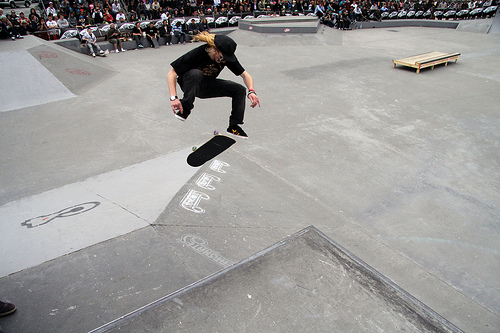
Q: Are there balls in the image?
A: No, there are no balls.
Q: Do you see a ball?
A: No, there are no balls.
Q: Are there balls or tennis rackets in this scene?
A: No, there are no balls or tennis rackets.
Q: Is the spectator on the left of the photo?
A: Yes, the spectator is on the left of the image.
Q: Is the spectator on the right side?
A: No, the spectator is on the left of the image.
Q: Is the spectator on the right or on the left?
A: The spectator is on the left of the image.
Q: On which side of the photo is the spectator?
A: The spectator is on the left of the image.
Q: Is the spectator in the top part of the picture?
A: Yes, the spectator is in the top of the image.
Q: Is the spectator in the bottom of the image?
A: No, the spectator is in the top of the image.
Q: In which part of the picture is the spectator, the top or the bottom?
A: The spectator is in the top of the image.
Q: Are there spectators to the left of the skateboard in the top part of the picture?
A: Yes, there is a spectator to the left of the skateboard.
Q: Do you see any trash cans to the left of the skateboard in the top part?
A: No, there is a spectator to the left of the skateboard.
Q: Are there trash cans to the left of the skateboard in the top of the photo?
A: No, there is a spectator to the left of the skateboard.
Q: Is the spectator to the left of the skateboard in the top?
A: Yes, the spectator is to the left of the skateboard.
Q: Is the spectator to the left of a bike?
A: No, the spectator is to the left of the skateboard.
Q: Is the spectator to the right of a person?
A: No, the spectator is to the left of a person.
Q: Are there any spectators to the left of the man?
A: Yes, there is a spectator to the left of the man.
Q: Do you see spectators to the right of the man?
A: No, the spectator is to the left of the man.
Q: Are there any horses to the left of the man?
A: No, there is a spectator to the left of the man.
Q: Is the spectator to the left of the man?
A: Yes, the spectator is to the left of the man.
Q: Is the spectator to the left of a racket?
A: No, the spectator is to the left of the man.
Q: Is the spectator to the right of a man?
A: No, the spectator is to the left of a man.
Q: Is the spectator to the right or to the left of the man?
A: The spectator is to the left of the man.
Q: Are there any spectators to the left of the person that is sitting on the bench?
A: Yes, there is a spectator to the left of the person.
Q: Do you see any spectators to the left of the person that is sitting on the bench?
A: Yes, there is a spectator to the left of the person.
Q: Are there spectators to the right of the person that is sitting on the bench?
A: No, the spectator is to the left of the person.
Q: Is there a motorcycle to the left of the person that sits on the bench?
A: No, there is a spectator to the left of the person.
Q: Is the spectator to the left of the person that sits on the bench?
A: Yes, the spectator is to the left of the person.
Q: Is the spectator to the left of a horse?
A: No, the spectator is to the left of the person.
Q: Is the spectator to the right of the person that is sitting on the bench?
A: No, the spectator is to the left of the person.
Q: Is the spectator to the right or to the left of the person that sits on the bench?
A: The spectator is to the left of the person.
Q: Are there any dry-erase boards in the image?
A: No, there are no dry-erase boards.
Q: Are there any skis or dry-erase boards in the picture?
A: No, there are no dry-erase boards or skis.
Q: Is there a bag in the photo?
A: No, there are no bags.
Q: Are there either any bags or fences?
A: No, there are no bags or fences.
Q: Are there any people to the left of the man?
A: Yes, there is a person to the left of the man.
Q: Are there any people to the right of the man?
A: No, the person is to the left of the man.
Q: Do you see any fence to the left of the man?
A: No, there is a person to the left of the man.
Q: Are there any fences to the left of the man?
A: No, there is a person to the left of the man.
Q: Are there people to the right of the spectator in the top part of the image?
A: Yes, there is a person to the right of the spectator.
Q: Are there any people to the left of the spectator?
A: No, the person is to the right of the spectator.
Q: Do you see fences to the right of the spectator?
A: No, there is a person to the right of the spectator.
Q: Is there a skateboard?
A: Yes, there is a skateboard.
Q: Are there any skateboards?
A: Yes, there is a skateboard.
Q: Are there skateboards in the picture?
A: Yes, there is a skateboard.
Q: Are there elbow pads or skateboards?
A: Yes, there is a skateboard.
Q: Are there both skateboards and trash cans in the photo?
A: No, there is a skateboard but no trash cans.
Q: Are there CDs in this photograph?
A: No, there are no cds.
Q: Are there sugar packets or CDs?
A: No, there are no CDs or sugar packets.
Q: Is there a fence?
A: No, there are no fences.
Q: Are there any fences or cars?
A: No, there are no fences or cars.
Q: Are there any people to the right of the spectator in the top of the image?
A: Yes, there is a person to the right of the spectator.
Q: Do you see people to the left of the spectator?
A: No, the person is to the right of the spectator.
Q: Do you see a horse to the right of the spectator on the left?
A: No, there is a person to the right of the spectator.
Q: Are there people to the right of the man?
A: No, the person is to the left of the man.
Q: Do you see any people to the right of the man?
A: No, the person is to the left of the man.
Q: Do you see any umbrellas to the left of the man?
A: No, there is a person to the left of the man.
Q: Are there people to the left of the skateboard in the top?
A: Yes, there is a person to the left of the skateboard.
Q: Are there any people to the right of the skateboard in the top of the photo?
A: No, the person is to the left of the skateboard.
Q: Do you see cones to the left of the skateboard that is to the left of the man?
A: No, there is a person to the left of the skateboard.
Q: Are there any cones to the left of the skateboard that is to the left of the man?
A: No, there is a person to the left of the skateboard.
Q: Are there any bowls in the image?
A: No, there are no bowls.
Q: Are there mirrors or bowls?
A: No, there are no bowls or mirrors.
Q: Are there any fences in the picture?
A: No, there are no fences.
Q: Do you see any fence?
A: No, there are no fences.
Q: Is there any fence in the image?
A: No, there are no fences.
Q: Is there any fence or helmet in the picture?
A: No, there are no fences or helmets.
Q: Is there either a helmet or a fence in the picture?
A: No, there are no fences or helmets.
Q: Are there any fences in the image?
A: No, there are no fences.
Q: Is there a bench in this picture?
A: Yes, there is a bench.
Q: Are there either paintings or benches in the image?
A: Yes, there is a bench.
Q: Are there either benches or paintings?
A: Yes, there is a bench.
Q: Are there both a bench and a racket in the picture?
A: No, there is a bench but no rackets.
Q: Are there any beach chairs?
A: No, there are no beach chairs.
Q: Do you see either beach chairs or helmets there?
A: No, there are no beach chairs or helmets.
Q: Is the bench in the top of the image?
A: Yes, the bench is in the top of the image.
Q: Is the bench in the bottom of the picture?
A: No, the bench is in the top of the image.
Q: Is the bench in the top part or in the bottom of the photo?
A: The bench is in the top of the image.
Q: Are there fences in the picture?
A: No, there are no fences.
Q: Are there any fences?
A: No, there are no fences.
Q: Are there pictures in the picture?
A: No, there are no pictures.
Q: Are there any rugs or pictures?
A: No, there are no pictures or rugs.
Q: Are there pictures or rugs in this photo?
A: No, there are no pictures or rugs.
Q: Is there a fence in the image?
A: No, there are no fences.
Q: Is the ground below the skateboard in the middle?
A: Yes, the ground is below the skateboard.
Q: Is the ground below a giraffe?
A: No, the ground is below the skateboard.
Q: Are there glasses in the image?
A: No, there are no glasses.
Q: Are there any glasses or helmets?
A: No, there are no glasses or helmets.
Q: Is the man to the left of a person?
A: No, the man is to the right of a person.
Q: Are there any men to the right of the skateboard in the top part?
A: Yes, there is a man to the right of the skateboard.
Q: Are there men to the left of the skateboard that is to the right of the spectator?
A: No, the man is to the right of the skateboard.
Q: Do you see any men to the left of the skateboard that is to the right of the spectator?
A: No, the man is to the right of the skateboard.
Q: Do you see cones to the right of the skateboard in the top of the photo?
A: No, there is a man to the right of the skateboard.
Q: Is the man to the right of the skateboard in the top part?
A: Yes, the man is to the right of the skateboard.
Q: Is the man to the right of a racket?
A: No, the man is to the right of the skateboard.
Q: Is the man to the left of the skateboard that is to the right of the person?
A: No, the man is to the right of the skateboard.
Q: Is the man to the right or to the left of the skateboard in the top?
A: The man is to the right of the skateboard.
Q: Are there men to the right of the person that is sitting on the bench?
A: Yes, there is a man to the right of the person.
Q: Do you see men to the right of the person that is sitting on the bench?
A: Yes, there is a man to the right of the person.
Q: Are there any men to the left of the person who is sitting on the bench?
A: No, the man is to the right of the person.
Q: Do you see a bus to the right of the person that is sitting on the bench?
A: No, there is a man to the right of the person.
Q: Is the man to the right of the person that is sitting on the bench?
A: Yes, the man is to the right of the person.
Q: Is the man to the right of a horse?
A: No, the man is to the right of the person.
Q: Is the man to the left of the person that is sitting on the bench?
A: No, the man is to the right of the person.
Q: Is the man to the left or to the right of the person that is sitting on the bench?
A: The man is to the right of the person.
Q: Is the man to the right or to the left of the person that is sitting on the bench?
A: The man is to the right of the person.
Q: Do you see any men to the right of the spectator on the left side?
A: Yes, there is a man to the right of the spectator.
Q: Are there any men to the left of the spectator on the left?
A: No, the man is to the right of the spectator.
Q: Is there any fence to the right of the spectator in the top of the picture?
A: No, there is a man to the right of the spectator.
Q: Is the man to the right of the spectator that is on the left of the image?
A: Yes, the man is to the right of the spectator.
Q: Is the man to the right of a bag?
A: No, the man is to the right of the spectator.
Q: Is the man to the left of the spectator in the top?
A: No, the man is to the right of the spectator.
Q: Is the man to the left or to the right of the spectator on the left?
A: The man is to the right of the spectator.